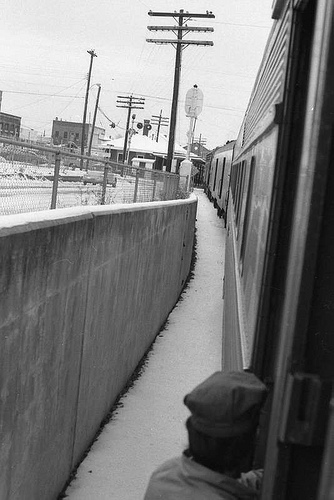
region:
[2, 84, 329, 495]
train stopped by a curved cement wall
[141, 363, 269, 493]
person wearing cap at train doorway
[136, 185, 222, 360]
snow-covered path between wall and train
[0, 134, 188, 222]
metal fencing on top of solid wall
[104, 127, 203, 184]
waiting shelter in front of train building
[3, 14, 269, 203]
line of poles connected to wires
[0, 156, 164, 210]
car on road by train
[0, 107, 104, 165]
plain and detailed boxy buildings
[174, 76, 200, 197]
base and pole supporting sign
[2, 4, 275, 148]
bright sky over town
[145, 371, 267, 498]
Person hanging onto side of train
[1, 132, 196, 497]
retainer wall goes deep into ground surrounding train tracks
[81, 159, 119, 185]
older style car in motion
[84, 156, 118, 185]
car driving along side train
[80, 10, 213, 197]
wooden poles cary power lines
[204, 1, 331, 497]
train moving in motion down tracks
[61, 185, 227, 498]
snow covering the ground alongside train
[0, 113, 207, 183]
buildings in the background of photo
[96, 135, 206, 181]
train station built beside train tracks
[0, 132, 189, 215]
metal fence to detour people from being around train tracks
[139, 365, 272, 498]
train worker at side of train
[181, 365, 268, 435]
dark train engineer's cap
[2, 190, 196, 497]
cement wall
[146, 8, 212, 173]
wooden telephone pole with three horizontal crossarms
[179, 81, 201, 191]
train equipment signal pole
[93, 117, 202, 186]
trainstation buildings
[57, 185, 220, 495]
snow and ice covers the ground beside a train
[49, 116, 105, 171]
multi-story brick building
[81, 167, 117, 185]
single car on a snowy street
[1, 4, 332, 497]
a train pulled into a city train station in winter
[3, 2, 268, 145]
light in daytime sky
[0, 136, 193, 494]
chain link fence on wall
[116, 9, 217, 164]
lines on telephone poles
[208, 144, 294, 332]
windows on side of train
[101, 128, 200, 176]
snow covered rooves of buildings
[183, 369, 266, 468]
hat on person's head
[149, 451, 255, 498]
turned up collar on coat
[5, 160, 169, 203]
car driving on street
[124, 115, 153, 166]
traffic lights on pole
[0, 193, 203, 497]
cement wall with snow on top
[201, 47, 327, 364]
passenger train on tracks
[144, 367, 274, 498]
man getting on train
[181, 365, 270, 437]
train engineer hat on man's head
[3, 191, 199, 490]
cement wall runs along tracks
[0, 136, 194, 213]
chain link fence above wall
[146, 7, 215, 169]
tall wooden electric pole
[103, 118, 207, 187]
train depot next to tracks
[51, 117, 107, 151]
old brick factory building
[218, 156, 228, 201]
window on side of passenger train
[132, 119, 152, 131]
railroad crossing lights